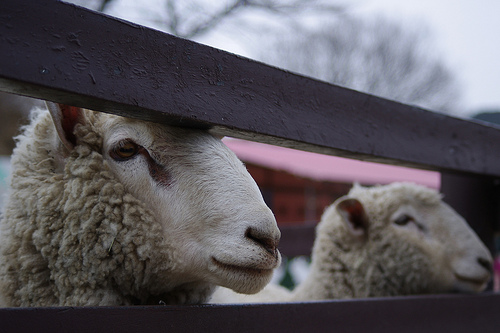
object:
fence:
[1, 0, 500, 178]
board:
[0, 292, 500, 331]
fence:
[0, 0, 500, 332]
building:
[215, 132, 441, 257]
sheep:
[0, 98, 284, 307]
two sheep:
[0, 77, 499, 312]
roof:
[210, 132, 447, 189]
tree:
[265, 9, 465, 119]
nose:
[244, 218, 286, 253]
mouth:
[208, 250, 283, 285]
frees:
[93, 0, 498, 122]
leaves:
[325, 26, 334, 34]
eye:
[101, 128, 149, 164]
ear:
[40, 101, 102, 155]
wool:
[0, 102, 174, 308]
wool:
[287, 182, 436, 298]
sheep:
[275, 181, 495, 298]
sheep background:
[289, 181, 493, 305]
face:
[94, 109, 275, 263]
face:
[382, 189, 493, 278]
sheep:
[277, 181, 496, 305]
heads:
[0, 78, 282, 305]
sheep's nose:
[472, 253, 497, 276]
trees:
[158, 1, 321, 53]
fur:
[10, 159, 109, 312]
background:
[1, 0, 500, 332]